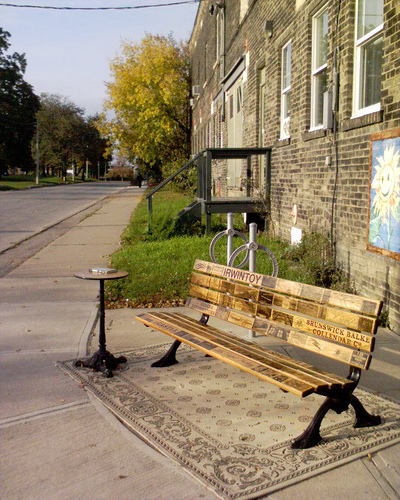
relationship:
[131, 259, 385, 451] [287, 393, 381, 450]
bench has legs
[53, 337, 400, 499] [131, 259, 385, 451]
rug under bench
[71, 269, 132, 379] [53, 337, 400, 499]
table on rug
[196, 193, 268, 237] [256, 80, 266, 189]
platform front of door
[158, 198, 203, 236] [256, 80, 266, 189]
stairs leading to door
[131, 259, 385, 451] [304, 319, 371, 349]
bench has words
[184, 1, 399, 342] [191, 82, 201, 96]
wall has air conditioner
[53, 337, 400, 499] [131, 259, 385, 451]
rug underneath bench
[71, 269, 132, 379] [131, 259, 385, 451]
table next to bench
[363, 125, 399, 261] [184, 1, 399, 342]
painting on wall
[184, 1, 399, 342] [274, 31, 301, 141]
wall has window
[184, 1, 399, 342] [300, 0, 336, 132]
wall has window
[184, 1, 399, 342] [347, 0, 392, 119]
wall has window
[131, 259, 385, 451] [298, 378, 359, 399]
bench has edge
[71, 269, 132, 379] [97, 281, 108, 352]
table has stand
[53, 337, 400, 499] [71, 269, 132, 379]
rug underneath table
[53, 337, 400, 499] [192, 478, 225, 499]
rug has edge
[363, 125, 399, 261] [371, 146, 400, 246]
painting has sunflower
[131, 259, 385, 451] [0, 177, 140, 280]
bench next to road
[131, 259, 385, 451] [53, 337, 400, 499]
bench on rug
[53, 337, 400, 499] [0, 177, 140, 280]
rug on corner of road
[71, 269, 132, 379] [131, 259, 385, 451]
table near bench